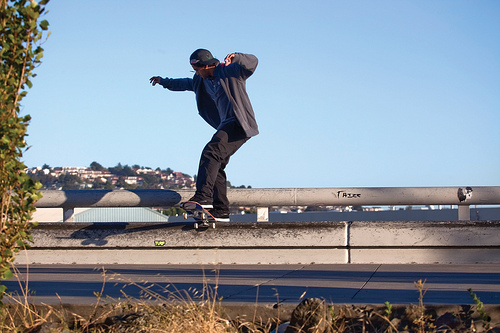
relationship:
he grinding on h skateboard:
[149, 49, 260, 222] [179, 203, 230, 233]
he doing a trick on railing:
[149, 49, 260, 222] [17, 192, 498, 273]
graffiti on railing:
[334, 191, 372, 208] [227, 185, 497, 202]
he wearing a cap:
[149, 49, 260, 222] [189, 49, 229, 81]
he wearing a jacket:
[149, 49, 260, 222] [168, 55, 268, 135]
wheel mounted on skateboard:
[181, 211, 189, 219] [178, 198, 220, 233]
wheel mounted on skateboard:
[192, 220, 200, 230] [178, 198, 220, 233]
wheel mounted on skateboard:
[199, 211, 206, 218] [178, 198, 220, 233]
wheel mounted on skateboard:
[210, 221, 217, 228] [178, 198, 220, 233]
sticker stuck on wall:
[143, 234, 170, 252] [11, 218, 484, 268]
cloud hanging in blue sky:
[22, 81, 318, 186] [20, 2, 499, 184]